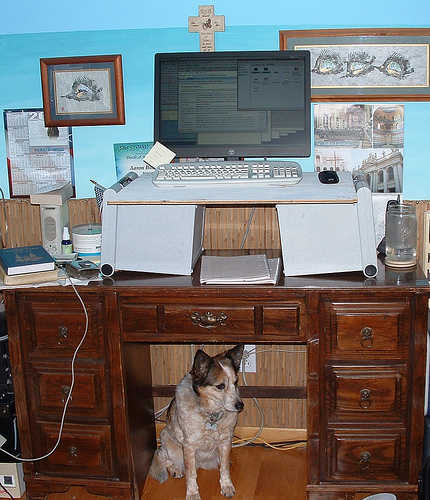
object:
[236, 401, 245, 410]
nose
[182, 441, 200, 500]
leg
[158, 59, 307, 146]
monitor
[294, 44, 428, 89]
picture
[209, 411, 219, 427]
tag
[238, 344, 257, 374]
outlet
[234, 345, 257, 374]
electrical outlet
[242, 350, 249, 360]
plug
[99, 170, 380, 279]
wooden desk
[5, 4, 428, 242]
wall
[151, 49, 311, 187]
computer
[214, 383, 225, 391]
eye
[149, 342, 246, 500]
dog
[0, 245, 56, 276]
book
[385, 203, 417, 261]
jar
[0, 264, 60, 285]
book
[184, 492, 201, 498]
foot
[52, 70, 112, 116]
picture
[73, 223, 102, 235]
discs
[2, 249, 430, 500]
desk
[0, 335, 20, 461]
computer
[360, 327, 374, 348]
handle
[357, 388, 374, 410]
handle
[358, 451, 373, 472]
handle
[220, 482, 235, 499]
claw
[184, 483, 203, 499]
claw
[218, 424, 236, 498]
leg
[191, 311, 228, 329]
handle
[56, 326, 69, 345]
handle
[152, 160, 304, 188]
keyboard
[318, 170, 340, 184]
phone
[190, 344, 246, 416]
head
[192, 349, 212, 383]
ear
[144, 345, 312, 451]
background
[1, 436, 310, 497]
floor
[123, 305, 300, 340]
drawer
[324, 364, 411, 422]
drawer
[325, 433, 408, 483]
drawer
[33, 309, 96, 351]
drawer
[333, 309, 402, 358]
drawers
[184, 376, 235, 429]
neck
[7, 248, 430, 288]
surface